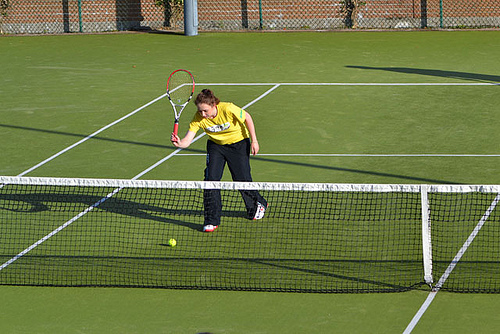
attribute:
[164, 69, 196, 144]
tennis racket — orange, white, red, black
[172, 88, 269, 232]
woman — playing tennis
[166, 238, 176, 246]
tennis ball — bright green, yellow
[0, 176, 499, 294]
net — white, black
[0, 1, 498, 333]
tennis court — green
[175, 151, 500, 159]
line — white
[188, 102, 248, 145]
shirt — yellow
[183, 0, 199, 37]
pole — gray, metal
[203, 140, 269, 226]
pants — black, jogging pants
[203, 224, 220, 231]
tennis shoe — white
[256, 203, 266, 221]
tennis shoe — white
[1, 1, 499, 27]
fence — chain link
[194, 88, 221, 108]
hair — brown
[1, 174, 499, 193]
trim — white